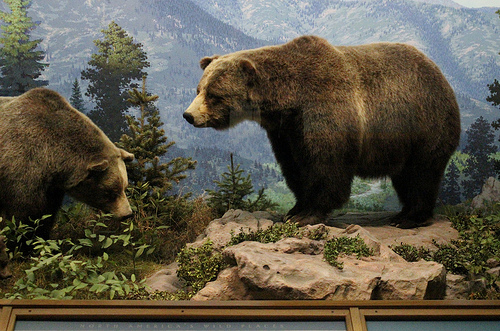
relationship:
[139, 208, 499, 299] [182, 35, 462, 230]
rock under bear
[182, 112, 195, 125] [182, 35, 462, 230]
nose of bear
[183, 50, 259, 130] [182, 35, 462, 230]
head of bear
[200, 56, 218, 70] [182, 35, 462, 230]
ear of bear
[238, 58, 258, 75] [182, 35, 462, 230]
ear of bear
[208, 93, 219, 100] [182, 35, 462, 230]
eye of bear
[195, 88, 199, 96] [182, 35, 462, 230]
eye of bear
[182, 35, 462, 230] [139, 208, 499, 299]
bear on rock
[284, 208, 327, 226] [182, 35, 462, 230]
paw of bear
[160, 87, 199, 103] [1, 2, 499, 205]
trees growing on mountains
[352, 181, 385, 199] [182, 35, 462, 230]
river under bear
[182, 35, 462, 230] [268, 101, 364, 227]
bear on legs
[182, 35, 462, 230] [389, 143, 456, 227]
bear on legs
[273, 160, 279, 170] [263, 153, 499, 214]
pine tree growing in field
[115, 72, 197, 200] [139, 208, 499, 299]
tree behind rock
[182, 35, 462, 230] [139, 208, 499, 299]
bear standing on rock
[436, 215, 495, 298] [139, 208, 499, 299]
shrub by rock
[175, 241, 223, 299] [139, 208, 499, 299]
shrub by rock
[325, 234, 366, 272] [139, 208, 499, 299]
ground cover growing on rock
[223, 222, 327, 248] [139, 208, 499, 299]
ground cover growing on rock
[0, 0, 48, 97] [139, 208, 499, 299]
tree below rock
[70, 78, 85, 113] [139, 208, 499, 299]
tree below rock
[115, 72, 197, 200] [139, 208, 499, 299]
tree below rock